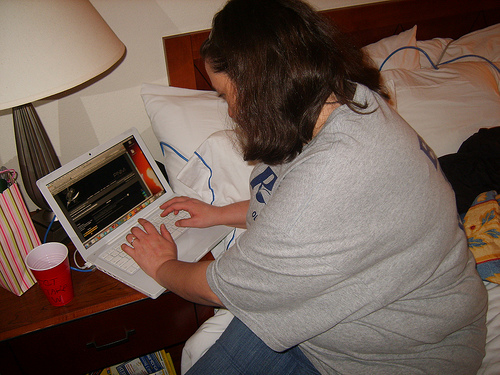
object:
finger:
[130, 226, 147, 240]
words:
[43, 277, 58, 286]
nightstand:
[0, 209, 217, 375]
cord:
[378, 46, 500, 74]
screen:
[46, 134, 166, 250]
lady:
[120, 0, 489, 375]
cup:
[25, 242, 76, 307]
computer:
[35, 126, 235, 299]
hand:
[121, 218, 178, 279]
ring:
[130, 236, 137, 244]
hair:
[199, 0, 392, 166]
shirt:
[208, 80, 489, 374]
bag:
[1, 165, 43, 296]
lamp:
[1, 0, 129, 246]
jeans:
[185, 316, 324, 375]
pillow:
[376, 61, 500, 159]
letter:
[249, 165, 279, 205]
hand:
[159, 196, 218, 229]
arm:
[121, 167, 347, 309]